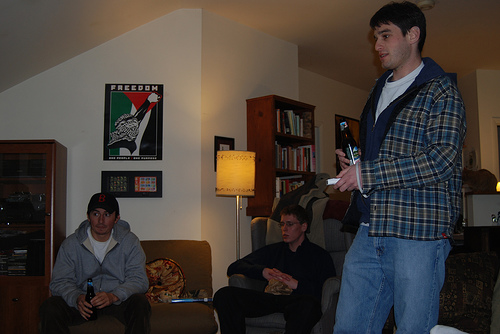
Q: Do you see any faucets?
A: No, there are no faucets.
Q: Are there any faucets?
A: No, there are no faucets.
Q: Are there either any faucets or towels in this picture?
A: No, there are no faucets or towels.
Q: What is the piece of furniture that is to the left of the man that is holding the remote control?
A: The piece of furniture is a shelf.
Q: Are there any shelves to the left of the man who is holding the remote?
A: Yes, there is a shelf to the left of the man.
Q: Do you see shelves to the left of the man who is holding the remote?
A: Yes, there is a shelf to the left of the man.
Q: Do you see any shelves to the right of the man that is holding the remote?
A: No, the shelf is to the left of the man.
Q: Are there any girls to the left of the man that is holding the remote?
A: No, there is a shelf to the left of the man.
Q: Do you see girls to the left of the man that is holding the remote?
A: No, there is a shelf to the left of the man.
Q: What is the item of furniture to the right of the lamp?
A: The piece of furniture is a shelf.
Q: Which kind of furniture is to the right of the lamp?
A: The piece of furniture is a shelf.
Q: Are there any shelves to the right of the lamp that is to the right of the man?
A: Yes, there is a shelf to the right of the lamp.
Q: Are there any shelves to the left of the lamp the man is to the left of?
A: No, the shelf is to the right of the lamp.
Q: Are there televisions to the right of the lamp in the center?
A: No, there is a shelf to the right of the lamp.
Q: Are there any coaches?
A: No, there are no coaches.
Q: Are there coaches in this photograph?
A: No, there are no coaches.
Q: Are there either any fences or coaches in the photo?
A: No, there are no coaches or fences.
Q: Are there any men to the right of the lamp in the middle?
A: Yes, there is a man to the right of the lamp.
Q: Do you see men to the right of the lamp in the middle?
A: Yes, there is a man to the right of the lamp.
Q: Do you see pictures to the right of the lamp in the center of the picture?
A: No, there is a man to the right of the lamp.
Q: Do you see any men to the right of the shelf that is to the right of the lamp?
A: Yes, there is a man to the right of the shelf.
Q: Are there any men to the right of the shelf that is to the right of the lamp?
A: Yes, there is a man to the right of the shelf.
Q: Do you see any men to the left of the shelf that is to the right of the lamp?
A: No, the man is to the right of the shelf.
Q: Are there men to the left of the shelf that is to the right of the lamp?
A: No, the man is to the right of the shelf.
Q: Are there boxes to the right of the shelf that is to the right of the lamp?
A: No, there is a man to the right of the shelf.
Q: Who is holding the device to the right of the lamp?
A: The man is holding the remote control.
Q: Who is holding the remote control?
A: The man is holding the remote control.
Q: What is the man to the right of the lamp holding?
A: The man is holding the remote.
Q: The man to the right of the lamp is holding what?
A: The man is holding the remote.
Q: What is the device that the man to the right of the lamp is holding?
A: The device is a remote control.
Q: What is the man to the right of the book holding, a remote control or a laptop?
A: The man is holding a remote control.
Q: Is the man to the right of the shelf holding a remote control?
A: Yes, the man is holding a remote control.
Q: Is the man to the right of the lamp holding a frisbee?
A: No, the man is holding a remote control.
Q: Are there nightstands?
A: No, there are no nightstands.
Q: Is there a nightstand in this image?
A: No, there are no nightstands.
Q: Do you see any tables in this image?
A: No, there are no tables.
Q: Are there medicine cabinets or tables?
A: No, there are no tables or medicine cabinets.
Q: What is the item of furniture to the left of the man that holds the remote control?
A: The piece of furniture is a shelf.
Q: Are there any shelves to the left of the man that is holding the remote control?
A: Yes, there is a shelf to the left of the man.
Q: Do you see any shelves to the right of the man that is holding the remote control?
A: No, the shelf is to the left of the man.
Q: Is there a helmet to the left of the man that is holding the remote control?
A: No, there is a shelf to the left of the man.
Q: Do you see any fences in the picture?
A: No, there are no fences.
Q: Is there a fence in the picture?
A: No, there are no fences.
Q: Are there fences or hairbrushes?
A: No, there are no fences or hairbrushes.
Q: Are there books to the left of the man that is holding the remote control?
A: Yes, there is a book to the left of the man.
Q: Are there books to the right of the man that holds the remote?
A: No, the book is to the left of the man.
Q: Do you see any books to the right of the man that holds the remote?
A: No, the book is to the left of the man.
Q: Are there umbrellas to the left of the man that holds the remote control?
A: No, there is a book to the left of the man.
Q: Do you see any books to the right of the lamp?
A: Yes, there is a book to the right of the lamp.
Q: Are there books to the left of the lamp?
A: No, the book is to the right of the lamp.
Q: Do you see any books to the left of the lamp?
A: No, the book is to the right of the lamp.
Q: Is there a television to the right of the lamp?
A: No, there is a book to the right of the lamp.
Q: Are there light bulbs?
A: No, there are no light bulbs.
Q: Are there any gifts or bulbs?
A: No, there are no bulbs or gifts.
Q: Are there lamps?
A: Yes, there is a lamp.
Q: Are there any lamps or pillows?
A: Yes, there is a lamp.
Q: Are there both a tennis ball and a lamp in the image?
A: No, there is a lamp but no tennis balls.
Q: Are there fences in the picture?
A: No, there are no fences.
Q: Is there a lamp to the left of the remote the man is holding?
A: Yes, there is a lamp to the left of the remote control.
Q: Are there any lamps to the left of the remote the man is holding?
A: Yes, there is a lamp to the left of the remote control.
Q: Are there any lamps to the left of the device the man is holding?
A: Yes, there is a lamp to the left of the remote control.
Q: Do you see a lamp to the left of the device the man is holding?
A: Yes, there is a lamp to the left of the remote control.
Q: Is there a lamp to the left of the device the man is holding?
A: Yes, there is a lamp to the left of the remote control.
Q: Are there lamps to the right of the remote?
A: No, the lamp is to the left of the remote.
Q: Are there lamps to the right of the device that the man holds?
A: No, the lamp is to the left of the remote.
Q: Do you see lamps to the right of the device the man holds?
A: No, the lamp is to the left of the remote.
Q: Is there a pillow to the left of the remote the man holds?
A: No, there is a lamp to the left of the remote.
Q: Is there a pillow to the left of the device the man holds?
A: No, there is a lamp to the left of the remote.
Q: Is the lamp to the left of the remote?
A: Yes, the lamp is to the left of the remote.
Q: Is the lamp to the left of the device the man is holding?
A: Yes, the lamp is to the left of the remote.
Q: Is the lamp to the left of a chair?
A: No, the lamp is to the left of the remote.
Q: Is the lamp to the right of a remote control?
A: No, the lamp is to the left of a remote control.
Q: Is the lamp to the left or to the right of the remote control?
A: The lamp is to the left of the remote control.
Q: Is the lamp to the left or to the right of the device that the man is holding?
A: The lamp is to the left of the remote control.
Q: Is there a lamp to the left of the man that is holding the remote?
A: Yes, there is a lamp to the left of the man.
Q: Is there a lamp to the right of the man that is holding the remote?
A: No, the lamp is to the left of the man.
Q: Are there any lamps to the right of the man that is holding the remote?
A: No, the lamp is to the left of the man.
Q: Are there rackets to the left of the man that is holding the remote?
A: No, there is a lamp to the left of the man.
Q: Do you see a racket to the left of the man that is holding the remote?
A: No, there is a lamp to the left of the man.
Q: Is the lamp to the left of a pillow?
A: No, the lamp is to the left of a man.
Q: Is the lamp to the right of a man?
A: No, the lamp is to the left of a man.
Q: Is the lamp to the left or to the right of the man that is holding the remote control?
A: The lamp is to the left of the man.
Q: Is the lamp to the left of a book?
A: Yes, the lamp is to the left of a book.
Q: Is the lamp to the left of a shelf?
A: Yes, the lamp is to the left of a shelf.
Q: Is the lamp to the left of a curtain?
A: No, the lamp is to the left of a shelf.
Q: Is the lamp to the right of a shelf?
A: No, the lamp is to the left of a shelf.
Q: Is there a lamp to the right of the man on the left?
A: Yes, there is a lamp to the right of the man.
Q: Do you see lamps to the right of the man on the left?
A: Yes, there is a lamp to the right of the man.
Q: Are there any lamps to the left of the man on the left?
A: No, the lamp is to the right of the man.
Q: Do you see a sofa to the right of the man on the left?
A: No, there is a lamp to the right of the man.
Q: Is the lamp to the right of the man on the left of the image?
A: Yes, the lamp is to the right of the man.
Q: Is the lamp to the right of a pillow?
A: No, the lamp is to the right of the man.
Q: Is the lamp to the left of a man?
A: No, the lamp is to the right of a man.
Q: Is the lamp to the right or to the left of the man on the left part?
A: The lamp is to the right of the man.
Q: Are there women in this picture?
A: No, there are no women.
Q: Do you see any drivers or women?
A: No, there are no women or drivers.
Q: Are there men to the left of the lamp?
A: Yes, there is a man to the left of the lamp.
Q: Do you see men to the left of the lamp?
A: Yes, there is a man to the left of the lamp.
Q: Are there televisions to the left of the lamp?
A: No, there is a man to the left of the lamp.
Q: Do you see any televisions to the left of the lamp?
A: No, there is a man to the left of the lamp.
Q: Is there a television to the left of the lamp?
A: No, there is a man to the left of the lamp.